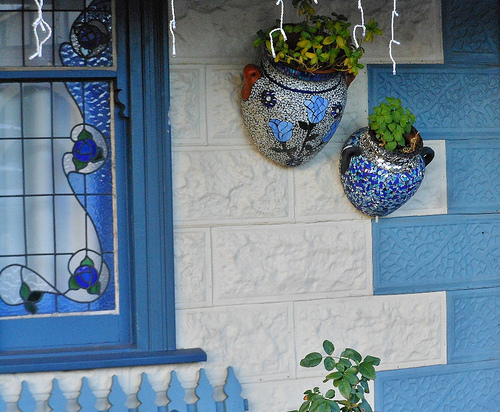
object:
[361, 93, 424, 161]
plants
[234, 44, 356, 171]
vase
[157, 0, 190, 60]
lights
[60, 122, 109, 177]
flowers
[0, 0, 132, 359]
window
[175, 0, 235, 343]
wall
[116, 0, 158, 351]
sill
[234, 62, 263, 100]
handle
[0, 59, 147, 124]
panes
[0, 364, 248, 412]
fence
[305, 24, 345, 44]
leaves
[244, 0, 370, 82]
plant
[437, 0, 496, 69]
tile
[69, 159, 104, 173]
leaf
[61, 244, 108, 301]
rose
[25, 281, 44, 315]
leaves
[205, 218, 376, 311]
bricks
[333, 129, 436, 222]
pot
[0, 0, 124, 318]
decoration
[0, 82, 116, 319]
glass